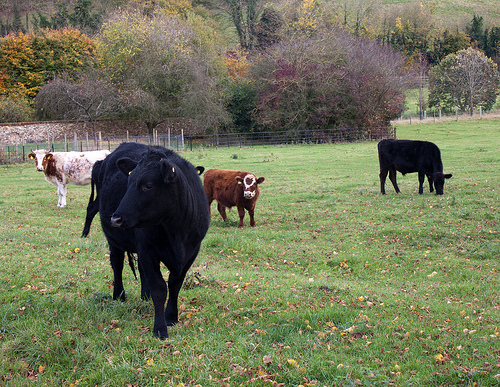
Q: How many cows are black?
A: Two.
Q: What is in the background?
A: Trees.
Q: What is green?
A: Grass.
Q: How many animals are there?
A: Four.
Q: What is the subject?
A: Cows.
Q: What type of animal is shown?
A: Cows.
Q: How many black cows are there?
A: Two.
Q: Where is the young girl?
A: No girl.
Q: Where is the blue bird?
A: No bird.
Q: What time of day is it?
A: Afternoon.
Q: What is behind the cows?
A: Fence.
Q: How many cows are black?
A: Two.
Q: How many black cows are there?
A: 2.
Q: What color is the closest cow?
A: Black.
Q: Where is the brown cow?
A: In the middle.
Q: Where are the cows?
A: In a field.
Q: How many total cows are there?
A: 4.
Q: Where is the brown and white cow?
A: In back on the left.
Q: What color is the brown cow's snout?
A: White.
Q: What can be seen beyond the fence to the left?
A: Railroad tracks.